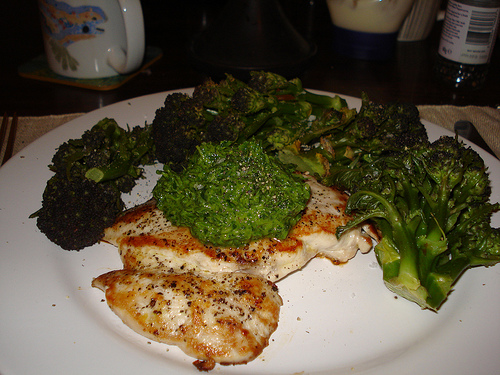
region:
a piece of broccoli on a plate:
[340, 136, 498, 315]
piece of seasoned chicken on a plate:
[87, 266, 275, 358]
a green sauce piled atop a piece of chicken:
[153, 141, 310, 247]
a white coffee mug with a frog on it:
[36, 0, 145, 81]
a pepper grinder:
[434, 0, 497, 98]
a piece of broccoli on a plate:
[40, 176, 122, 252]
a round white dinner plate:
[0, 86, 498, 374]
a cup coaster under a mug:
[19, 51, 171, 91]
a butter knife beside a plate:
[454, 118, 496, 158]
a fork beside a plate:
[0, 106, 20, 168]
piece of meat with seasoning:
[87, 258, 298, 363]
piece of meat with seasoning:
[102, 168, 388, 283]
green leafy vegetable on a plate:
[137, 135, 317, 252]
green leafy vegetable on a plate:
[336, 129, 498, 324]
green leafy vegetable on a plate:
[20, 100, 154, 262]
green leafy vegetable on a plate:
[137, 65, 355, 164]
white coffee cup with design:
[29, 0, 154, 86]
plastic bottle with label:
[433, 1, 498, 94]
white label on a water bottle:
[436, 2, 498, 69]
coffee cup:
[313, 0, 428, 42]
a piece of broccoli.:
[335, 124, 495, 309]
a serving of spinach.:
[148, 129, 315, 255]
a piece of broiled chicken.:
[79, 257, 298, 369]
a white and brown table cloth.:
[1, 105, 46, 140]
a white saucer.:
[297, 296, 419, 372]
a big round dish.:
[318, 317, 440, 370]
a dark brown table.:
[372, 51, 421, 97]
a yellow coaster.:
[15, 75, 130, 95]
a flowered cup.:
[25, 0, 165, 80]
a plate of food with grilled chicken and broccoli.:
[0, 14, 499, 373]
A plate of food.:
[0, 71, 498, 373]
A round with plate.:
[4, 87, 499, 373]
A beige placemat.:
[4, 104, 498, 154]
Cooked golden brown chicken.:
[90, 176, 380, 371]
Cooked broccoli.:
[31, 73, 496, 311]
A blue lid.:
[329, 31, 400, 65]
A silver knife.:
[452, 115, 498, 155]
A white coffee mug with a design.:
[40, 1, 144, 78]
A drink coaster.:
[19, 37, 165, 92]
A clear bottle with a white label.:
[435, 5, 497, 83]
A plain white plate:
[4, 76, 497, 360]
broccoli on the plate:
[32, 72, 498, 306]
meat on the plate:
[86, 178, 381, 369]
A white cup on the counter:
[41, 0, 156, 79]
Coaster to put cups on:
[15, 48, 162, 93]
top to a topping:
[330, 24, 405, 64]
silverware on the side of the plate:
[454, 117, 499, 161]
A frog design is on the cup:
[34, 3, 154, 82]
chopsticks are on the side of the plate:
[0, 109, 19, 166]